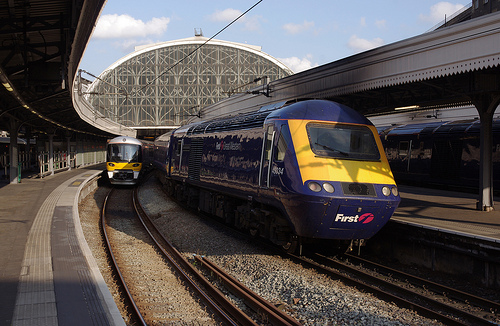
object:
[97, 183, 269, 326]
track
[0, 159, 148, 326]
platform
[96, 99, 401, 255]
two bikes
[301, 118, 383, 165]
windshield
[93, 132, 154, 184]
train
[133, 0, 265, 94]
power line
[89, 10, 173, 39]
cloud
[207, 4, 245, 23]
cloud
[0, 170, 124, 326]
sidewalk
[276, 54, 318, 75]
white clouds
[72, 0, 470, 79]
blue sky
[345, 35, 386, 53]
white clouds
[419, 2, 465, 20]
white clouds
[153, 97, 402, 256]
train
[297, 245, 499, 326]
track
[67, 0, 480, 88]
sky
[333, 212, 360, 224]
first